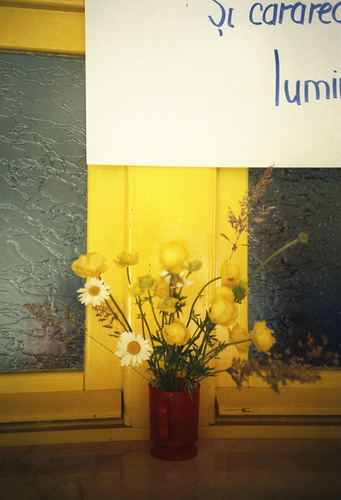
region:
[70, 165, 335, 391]
the flowers in the vase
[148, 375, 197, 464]
the red vase on the ground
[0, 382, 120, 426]
the yellow window seal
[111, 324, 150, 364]
the sunflower in the vase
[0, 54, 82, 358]
creases in the dark window cover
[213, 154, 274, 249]
the brush in the flower pot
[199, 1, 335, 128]
blue writing on the sign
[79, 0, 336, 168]
the white paper on the wall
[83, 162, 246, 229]
the yellow wall behind the vase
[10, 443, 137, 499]
the reflection in the top of the table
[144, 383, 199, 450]
that is a cup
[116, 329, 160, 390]
that is a flower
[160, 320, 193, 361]
that is a flower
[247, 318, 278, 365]
that is a flower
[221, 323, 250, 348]
that is a flower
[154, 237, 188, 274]
that is a flower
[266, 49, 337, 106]
writings on the wall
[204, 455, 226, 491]
section of the floor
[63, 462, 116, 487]
section of the floor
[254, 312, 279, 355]
part of a flower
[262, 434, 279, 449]
part of a floor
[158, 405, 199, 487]
part of a handkle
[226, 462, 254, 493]
part of a flooor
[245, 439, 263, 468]
part of a floor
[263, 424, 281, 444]
par tof a lone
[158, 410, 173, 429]
part of a handkle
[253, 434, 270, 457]
part of a floor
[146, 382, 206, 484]
this is a jug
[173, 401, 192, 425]
the jug is red in color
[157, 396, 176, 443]
this is the handle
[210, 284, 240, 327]
this is a flower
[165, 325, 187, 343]
the flower is yellow in color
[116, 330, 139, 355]
the flower is white in color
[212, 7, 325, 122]
this is a writing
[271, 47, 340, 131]
the writing is in blue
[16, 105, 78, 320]
this is the wall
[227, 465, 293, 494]
this is the floor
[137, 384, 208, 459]
the mug is made of plastic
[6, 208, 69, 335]
the window is made of glass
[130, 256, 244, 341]
the flowers are yellow in color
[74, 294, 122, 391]
the door oanes are yellow in color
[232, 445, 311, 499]
the floor is smooth and brown in color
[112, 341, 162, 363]
the flower is white in color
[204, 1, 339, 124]
words are written on a white board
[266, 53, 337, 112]
words are written in blue color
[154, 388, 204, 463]
the mug is maroon in color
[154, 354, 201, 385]
the stalks are green in color